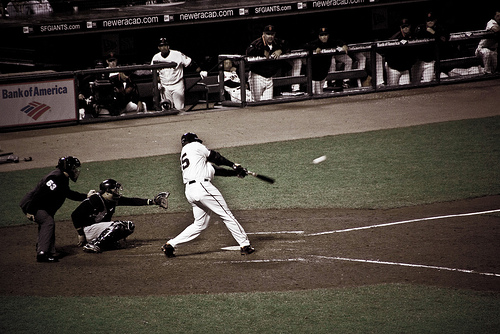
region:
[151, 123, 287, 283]
man wearing a helmet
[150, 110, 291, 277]
man wearing a white uniform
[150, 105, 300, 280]
man wearing uniform pants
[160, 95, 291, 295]
man holding a bat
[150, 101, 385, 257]
man hitting a ball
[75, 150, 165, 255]
man holding a glove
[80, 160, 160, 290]
man wearing a glove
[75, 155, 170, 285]
man squatting on field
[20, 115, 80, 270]
man weaing a helmet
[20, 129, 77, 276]
man wearing a uniform shirt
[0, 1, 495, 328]
a baseball game in progress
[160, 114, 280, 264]
a batter swinging at a baseball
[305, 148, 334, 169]
a white baseball moving through the air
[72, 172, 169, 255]
a catcher preparing to catch the ball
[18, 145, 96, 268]
umpire preparing to make a call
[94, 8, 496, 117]
baseball players observing the game in progress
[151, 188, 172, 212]
a brown baseball glove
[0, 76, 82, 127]
red and blue Bank of America advertisement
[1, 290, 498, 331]
green grass on the baseball field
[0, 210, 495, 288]
brown dirt on the baseball diamond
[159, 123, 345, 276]
a batter hitting a baseball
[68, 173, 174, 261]
the catcher on a baseball team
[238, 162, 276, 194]
a black and white baseball bat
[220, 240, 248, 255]
home-plate on a baseball field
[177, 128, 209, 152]
a black batter's helmet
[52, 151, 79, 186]
a black umpire's helmet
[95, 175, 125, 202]
a black catcher's helmet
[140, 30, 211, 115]
a professional baseball player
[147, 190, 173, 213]
the catcher's mitt on a professional baseball team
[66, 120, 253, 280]
two professional baseball players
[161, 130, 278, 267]
baseball player hitting ball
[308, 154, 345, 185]
baseball in mid air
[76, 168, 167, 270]
catcher behind the player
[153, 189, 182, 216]
glove on the player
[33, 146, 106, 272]
umpire behind the catcher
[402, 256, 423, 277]
white line on field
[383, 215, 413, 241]
white line on field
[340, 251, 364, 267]
white line on field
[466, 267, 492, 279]
white line on field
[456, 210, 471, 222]
white line on field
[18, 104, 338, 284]
A baseball game in progress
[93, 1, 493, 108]
Players in bullpen watching game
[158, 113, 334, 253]
Player at bat just hit the ball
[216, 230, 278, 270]
Home plate on ball field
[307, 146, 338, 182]
Ball is in motion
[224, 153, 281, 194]
Black baseball being swung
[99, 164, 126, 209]
Catcher is wearing a mask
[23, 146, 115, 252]
Umpire is behind the catcher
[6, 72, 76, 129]
Adevertising sin is red white and blue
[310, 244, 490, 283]
White lines painted on the field